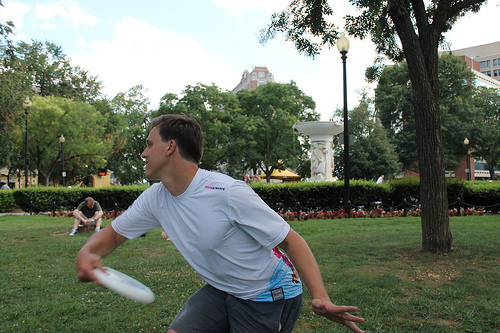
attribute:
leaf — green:
[1, 0, 498, 185]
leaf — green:
[288, 78, 296, 85]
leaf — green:
[202, 90, 207, 102]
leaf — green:
[28, 60, 106, 132]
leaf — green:
[117, 95, 122, 102]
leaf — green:
[191, 90, 196, 95]